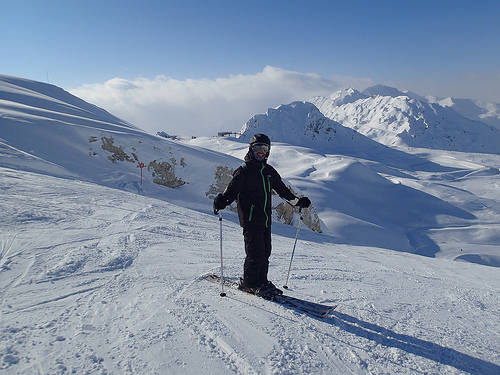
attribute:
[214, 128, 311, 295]
man — looking, skiing, smiling, posing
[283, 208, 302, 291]
ski pole — thin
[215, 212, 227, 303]
ski pole — thin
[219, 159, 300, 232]
jacket — warm, black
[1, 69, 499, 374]
area — snow covered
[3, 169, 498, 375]
snow — cold, white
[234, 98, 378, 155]
hill — snow covered, shadowed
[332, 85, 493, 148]
hill — snow covered, shadowed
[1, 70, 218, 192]
hill — snow covered, shadowed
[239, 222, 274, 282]
pants — black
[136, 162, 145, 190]
pole — orange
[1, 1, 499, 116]
sky — blue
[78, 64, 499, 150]
cloud — white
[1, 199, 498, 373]
ground — snow covered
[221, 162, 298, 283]
suit — black